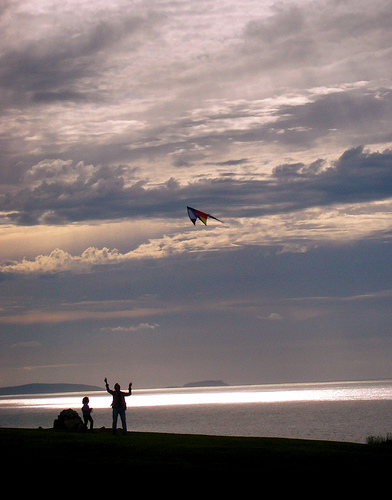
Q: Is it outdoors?
A: Yes, it is outdoors.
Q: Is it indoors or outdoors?
A: It is outdoors.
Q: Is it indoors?
A: No, it is outdoors.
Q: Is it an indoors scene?
A: No, it is outdoors.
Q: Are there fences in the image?
A: No, there are no fences.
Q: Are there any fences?
A: No, there are no fences.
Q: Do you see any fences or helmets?
A: No, there are no fences or helmets.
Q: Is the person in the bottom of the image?
A: Yes, the person is in the bottom of the image.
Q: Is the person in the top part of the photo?
A: No, the person is in the bottom of the image.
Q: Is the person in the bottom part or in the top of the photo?
A: The person is in the bottom of the image.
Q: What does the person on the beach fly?
A: The person flies the kite.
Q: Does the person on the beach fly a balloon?
A: No, the person flies a kite.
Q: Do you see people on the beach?
A: Yes, there is a person on the beach.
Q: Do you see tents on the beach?
A: No, there is a person on the beach.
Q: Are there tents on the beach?
A: No, there is a person on the beach.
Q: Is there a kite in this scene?
A: Yes, there is a kite.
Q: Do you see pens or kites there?
A: Yes, there is a kite.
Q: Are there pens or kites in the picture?
A: Yes, there is a kite.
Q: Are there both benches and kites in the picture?
A: No, there is a kite but no benches.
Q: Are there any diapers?
A: No, there are no diapers.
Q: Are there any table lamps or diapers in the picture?
A: No, there are no diapers or table lamps.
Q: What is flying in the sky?
A: The kite is flying in the sky.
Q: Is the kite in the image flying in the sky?
A: Yes, the kite is flying in the sky.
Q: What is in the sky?
A: The kite is in the sky.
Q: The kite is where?
A: The kite is in the sky.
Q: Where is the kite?
A: The kite is in the sky.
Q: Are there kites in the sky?
A: Yes, there is a kite in the sky.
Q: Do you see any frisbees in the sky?
A: No, there is a kite in the sky.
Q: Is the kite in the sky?
A: Yes, the kite is in the sky.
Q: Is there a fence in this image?
A: No, there are no fences.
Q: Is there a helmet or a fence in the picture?
A: No, there are no fences or helmets.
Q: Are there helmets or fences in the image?
A: No, there are no fences or helmets.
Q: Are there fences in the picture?
A: No, there are no fences.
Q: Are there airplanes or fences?
A: No, there are no fences or airplanes.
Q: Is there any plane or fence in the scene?
A: No, there are no fences or airplanes.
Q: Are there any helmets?
A: No, there are no helmets.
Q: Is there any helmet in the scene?
A: No, there are no helmets.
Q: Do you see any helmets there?
A: No, there are no helmets.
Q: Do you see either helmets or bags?
A: No, there are no helmets or bags.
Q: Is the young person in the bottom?
A: Yes, the person is in the bottom of the image.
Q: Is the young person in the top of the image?
A: No, the person is in the bottom of the image.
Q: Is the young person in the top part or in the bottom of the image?
A: The person is in the bottom of the image.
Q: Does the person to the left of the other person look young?
A: Yes, the person is young.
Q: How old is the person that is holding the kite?
A: The person is young.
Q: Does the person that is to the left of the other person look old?
A: No, the person is young.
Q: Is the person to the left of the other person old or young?
A: The person is young.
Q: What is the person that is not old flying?
A: The person is flying the kite.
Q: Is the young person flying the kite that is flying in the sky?
A: Yes, the person is flying the kite.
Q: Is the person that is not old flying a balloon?
A: No, the person is flying the kite.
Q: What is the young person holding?
A: The person is holding the kite.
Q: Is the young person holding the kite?
A: Yes, the person is holding the kite.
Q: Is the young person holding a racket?
A: No, the person is holding the kite.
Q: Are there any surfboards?
A: No, there are no surfboards.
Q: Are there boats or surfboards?
A: No, there are no surfboards or boats.